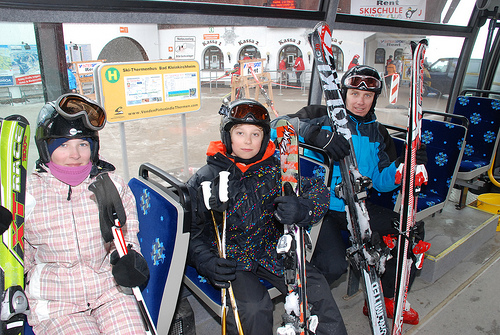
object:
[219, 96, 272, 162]
helmet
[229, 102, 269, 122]
goggles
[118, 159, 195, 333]
seat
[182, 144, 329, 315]
bus seat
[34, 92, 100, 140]
helmet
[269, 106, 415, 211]
jacket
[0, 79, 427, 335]
ski lift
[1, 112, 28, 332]
green skis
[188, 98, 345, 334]
boy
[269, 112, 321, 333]
skies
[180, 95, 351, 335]
man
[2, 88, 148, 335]
girl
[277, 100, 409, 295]
ski gear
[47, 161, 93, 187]
elephant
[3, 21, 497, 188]
outside window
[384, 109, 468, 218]
chair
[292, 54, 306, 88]
people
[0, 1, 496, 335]
bus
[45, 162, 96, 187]
pink scarf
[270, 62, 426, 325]
man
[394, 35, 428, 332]
skiis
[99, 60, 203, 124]
sign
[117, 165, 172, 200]
wall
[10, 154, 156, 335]
suit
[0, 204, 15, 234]
hand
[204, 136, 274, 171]
hood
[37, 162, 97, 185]
neck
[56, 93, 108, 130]
goggles